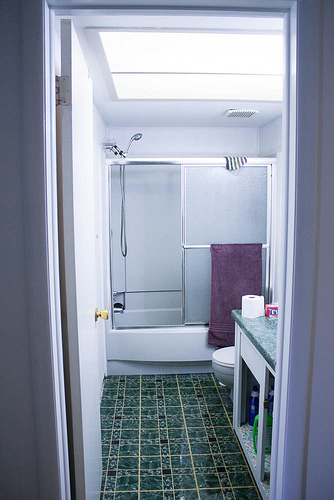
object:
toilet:
[212, 345, 237, 402]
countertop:
[231, 310, 278, 374]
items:
[256, 384, 268, 482]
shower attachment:
[112, 132, 143, 258]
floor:
[97, 371, 262, 500]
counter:
[231, 303, 280, 375]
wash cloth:
[224, 156, 248, 171]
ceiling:
[104, 100, 282, 129]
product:
[268, 384, 274, 414]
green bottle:
[253, 398, 273, 456]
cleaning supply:
[249, 385, 259, 426]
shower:
[101, 125, 278, 376]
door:
[181, 164, 271, 325]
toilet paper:
[242, 294, 265, 318]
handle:
[95, 308, 109, 322]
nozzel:
[113, 301, 124, 312]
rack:
[183, 243, 267, 248]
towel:
[206, 243, 263, 347]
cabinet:
[234, 321, 277, 500]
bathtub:
[106, 308, 236, 374]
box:
[265, 304, 278, 317]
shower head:
[124, 132, 142, 154]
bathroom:
[48, 6, 291, 500]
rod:
[182, 156, 277, 165]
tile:
[124, 399, 140, 408]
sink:
[232, 307, 280, 500]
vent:
[223, 109, 258, 120]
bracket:
[55, 75, 70, 107]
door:
[60, 16, 103, 500]